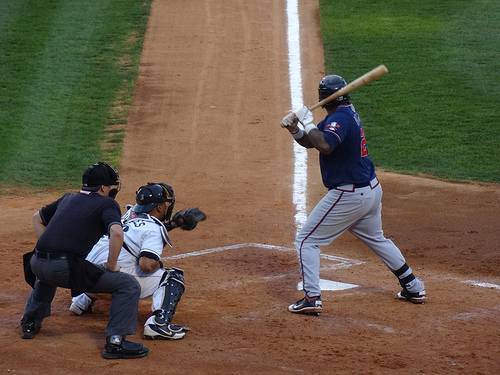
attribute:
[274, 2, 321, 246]
line — white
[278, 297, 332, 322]
clet — black, white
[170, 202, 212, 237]
mitt — dark, leather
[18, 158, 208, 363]
catcher — ready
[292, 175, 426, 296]
pants — striped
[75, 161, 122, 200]
face guard — dark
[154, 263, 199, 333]
protector — black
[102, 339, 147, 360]
shoes — shiny, black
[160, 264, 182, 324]
shin guard — black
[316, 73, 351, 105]
helmet — shiny, black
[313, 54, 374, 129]
helmet — blue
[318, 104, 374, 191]
shirt — blue